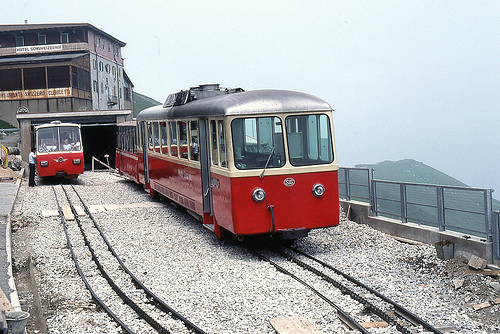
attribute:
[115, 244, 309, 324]
gravel — white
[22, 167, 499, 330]
rock — gray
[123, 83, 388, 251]
train — stopped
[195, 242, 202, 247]
rock — gray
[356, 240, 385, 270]
rock — gray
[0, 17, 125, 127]
old building — delapitated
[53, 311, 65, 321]
rock — gray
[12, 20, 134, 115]
building — old, delapitated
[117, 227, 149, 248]
rock — gray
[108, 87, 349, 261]
train — old, silver, red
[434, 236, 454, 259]
trash can — rusty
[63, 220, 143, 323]
train gravel — narrow, white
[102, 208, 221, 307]
rock — gray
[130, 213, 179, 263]
rock — gray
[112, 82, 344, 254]
train — parked, silver, red